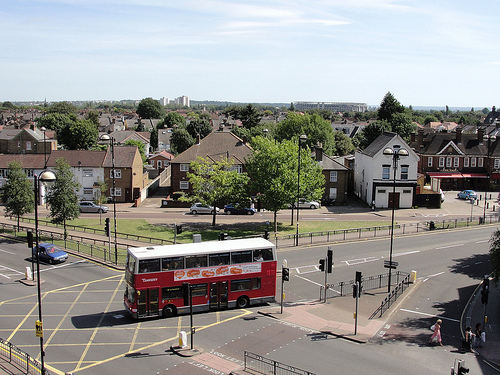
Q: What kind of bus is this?
A: Double decker.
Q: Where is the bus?
A: In an intersection.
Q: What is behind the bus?
A: Trees.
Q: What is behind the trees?
A: Houses.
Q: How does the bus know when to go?
A: Traffic signals.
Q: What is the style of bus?
A: Double decker.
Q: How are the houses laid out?
A: In a row.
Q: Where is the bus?
A: On the road.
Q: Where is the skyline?
A: Above the buildings.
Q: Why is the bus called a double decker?
A: Two levels.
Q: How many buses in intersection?
A: One.